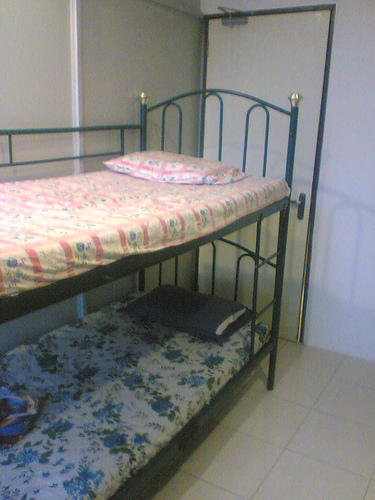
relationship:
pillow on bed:
[114, 282, 258, 344] [1, 293, 268, 497]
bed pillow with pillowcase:
[105, 150, 249, 186] [105, 148, 243, 183]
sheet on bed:
[16, 312, 259, 499] [7, 91, 315, 264]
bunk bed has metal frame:
[18, 137, 287, 484] [151, 86, 298, 295]